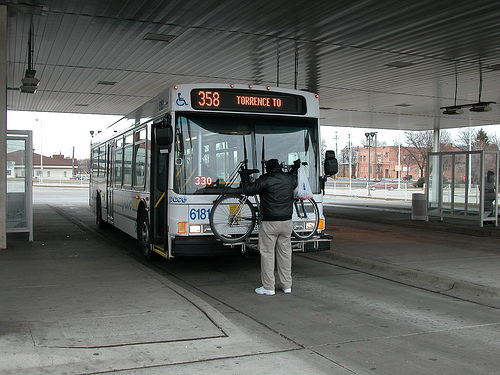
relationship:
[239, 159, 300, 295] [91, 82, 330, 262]
person in front of bus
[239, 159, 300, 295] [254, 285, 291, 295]
person wearing shoes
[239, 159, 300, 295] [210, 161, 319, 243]
person mounting bike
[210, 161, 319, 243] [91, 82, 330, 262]
bike being mounted on bus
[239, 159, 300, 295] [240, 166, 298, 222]
person wearing a coat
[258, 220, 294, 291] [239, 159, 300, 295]
pants on person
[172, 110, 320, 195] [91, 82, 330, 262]
windshield on bus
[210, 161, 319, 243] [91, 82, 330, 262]
bike being mounted to bus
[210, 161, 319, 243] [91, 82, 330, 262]
bike on bus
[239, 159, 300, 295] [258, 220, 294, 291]
person wearing pants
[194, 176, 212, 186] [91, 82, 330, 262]
330 on bus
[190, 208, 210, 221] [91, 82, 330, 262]
6181 on bus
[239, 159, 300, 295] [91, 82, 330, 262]
person putting bike on bus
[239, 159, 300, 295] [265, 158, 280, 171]
person wearing a hat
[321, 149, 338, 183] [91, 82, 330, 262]
mirror on bus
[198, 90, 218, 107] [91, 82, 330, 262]
358 on bus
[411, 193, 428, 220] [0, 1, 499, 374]
trash can at bus stop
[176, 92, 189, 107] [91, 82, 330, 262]
handicap symbol on bus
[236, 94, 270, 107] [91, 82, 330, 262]
torrence on bus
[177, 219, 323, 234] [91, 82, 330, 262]
lights on bus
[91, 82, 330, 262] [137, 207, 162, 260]
bus under tire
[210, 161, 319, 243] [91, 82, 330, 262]
bike at front of bus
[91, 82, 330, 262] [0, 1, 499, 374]
bus at bus stop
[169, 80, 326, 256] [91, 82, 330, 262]
front of bus